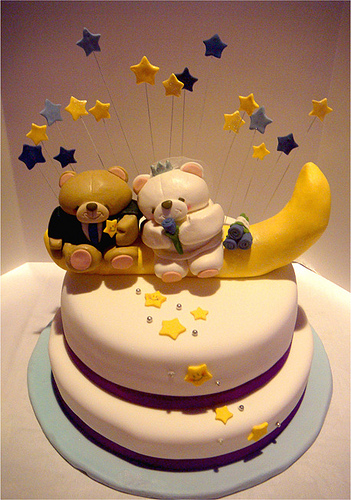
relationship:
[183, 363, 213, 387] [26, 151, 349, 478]
face on cake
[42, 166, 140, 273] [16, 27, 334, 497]
bear on top of cake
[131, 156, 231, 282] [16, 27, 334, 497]
bear on top of cake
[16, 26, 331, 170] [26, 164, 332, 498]
stars on top of cake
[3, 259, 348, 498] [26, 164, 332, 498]
tablecloth under cake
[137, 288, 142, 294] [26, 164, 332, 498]
metal dot on top of cake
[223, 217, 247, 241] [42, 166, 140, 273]
towel on side of bear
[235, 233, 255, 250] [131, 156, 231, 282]
towel on side of bear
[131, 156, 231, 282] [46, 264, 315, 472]
bear on top of cake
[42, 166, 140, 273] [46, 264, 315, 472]
bear on top of cake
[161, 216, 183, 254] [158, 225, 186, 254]
flower in holder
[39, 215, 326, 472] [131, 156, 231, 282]
cake decorated with bear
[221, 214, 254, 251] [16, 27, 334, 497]
flower on top of cake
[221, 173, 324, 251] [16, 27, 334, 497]
flower on top of cake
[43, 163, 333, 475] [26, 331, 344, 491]
cake sitting on plate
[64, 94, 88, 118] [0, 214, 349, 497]
yellow star over cake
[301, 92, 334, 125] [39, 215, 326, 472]
star over cake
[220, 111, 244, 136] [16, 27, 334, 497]
star over cake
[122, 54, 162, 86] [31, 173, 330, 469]
star over cake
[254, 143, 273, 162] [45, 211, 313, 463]
star over cake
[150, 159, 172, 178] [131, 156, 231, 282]
blue crown on bear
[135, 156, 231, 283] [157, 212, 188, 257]
bear holding flower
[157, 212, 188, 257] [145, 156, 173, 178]
flower with crown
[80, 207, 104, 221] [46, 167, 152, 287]
nose of bear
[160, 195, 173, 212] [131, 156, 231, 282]
brown nose of bear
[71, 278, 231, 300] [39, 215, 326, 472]
shadow on cake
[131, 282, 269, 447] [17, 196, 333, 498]
star on cake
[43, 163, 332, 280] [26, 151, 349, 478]
moon on top of cake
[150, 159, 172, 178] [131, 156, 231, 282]
blue crown on top of bear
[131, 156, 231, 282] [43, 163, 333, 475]
bear on top of cake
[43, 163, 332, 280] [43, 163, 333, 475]
moon on top of cake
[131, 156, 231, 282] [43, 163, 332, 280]
bear on top of moon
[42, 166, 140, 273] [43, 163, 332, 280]
bear on top of moon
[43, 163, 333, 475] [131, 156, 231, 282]
cake has bear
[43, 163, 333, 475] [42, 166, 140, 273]
cake has bear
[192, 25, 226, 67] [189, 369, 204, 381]
star has smiling face